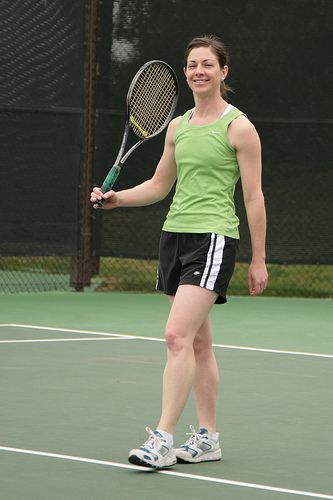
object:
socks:
[204, 430, 220, 446]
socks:
[154, 428, 174, 449]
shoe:
[172, 423, 222, 463]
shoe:
[127, 424, 178, 472]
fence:
[0, 0, 333, 300]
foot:
[127, 430, 178, 471]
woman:
[90, 35, 270, 473]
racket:
[94, 58, 181, 212]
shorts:
[154, 229, 240, 306]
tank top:
[160, 100, 248, 243]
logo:
[192, 270, 200, 275]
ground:
[1, 256, 333, 499]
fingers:
[101, 187, 115, 200]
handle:
[94, 163, 122, 211]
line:
[204, 232, 226, 293]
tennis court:
[1, 291, 333, 500]